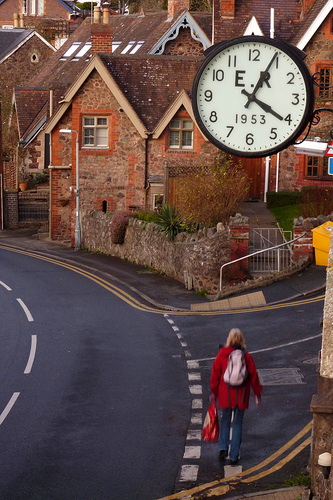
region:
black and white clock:
[191, 36, 311, 157]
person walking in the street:
[202, 327, 262, 465]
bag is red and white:
[199, 397, 220, 443]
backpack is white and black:
[221, 347, 250, 389]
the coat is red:
[209, 345, 262, 410]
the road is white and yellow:
[1, 242, 331, 499]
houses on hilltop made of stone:
[0, 1, 330, 246]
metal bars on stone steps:
[219, 232, 306, 297]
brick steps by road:
[17, 191, 50, 229]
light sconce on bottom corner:
[318, 451, 331, 480]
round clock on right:
[191, 36, 307, 152]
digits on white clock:
[208, 34, 299, 146]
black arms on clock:
[242, 72, 274, 126]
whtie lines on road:
[169, 390, 208, 467]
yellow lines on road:
[256, 411, 282, 483]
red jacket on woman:
[215, 352, 256, 411]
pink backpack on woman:
[223, 347, 253, 388]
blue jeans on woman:
[219, 410, 242, 451]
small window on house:
[82, 118, 117, 148]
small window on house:
[166, 118, 187, 146]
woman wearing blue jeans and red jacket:
[195, 326, 260, 466]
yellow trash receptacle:
[309, 222, 330, 270]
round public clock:
[191, 35, 317, 162]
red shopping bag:
[195, 403, 221, 442]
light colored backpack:
[220, 348, 249, 387]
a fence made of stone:
[72, 204, 331, 296]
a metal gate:
[252, 229, 294, 274]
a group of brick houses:
[2, 0, 331, 298]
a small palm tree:
[151, 204, 189, 244]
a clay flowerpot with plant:
[17, 172, 32, 193]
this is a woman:
[204, 327, 233, 450]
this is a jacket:
[200, 370, 287, 448]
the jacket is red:
[212, 386, 256, 399]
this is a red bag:
[187, 397, 215, 432]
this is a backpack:
[183, 342, 254, 404]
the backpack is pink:
[215, 333, 251, 399]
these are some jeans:
[211, 405, 237, 469]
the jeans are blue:
[213, 414, 242, 444]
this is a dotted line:
[156, 332, 168, 361]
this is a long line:
[230, 447, 289, 493]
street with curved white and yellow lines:
[2, 240, 329, 497]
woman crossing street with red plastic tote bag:
[198, 307, 266, 496]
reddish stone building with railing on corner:
[46, 77, 326, 314]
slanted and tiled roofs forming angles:
[1, 1, 332, 142]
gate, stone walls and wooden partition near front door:
[133, 154, 310, 291]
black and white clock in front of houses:
[142, 2, 331, 183]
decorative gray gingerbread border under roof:
[148, 9, 212, 62]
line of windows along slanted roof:
[24, 6, 143, 84]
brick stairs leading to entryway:
[10, 126, 54, 235]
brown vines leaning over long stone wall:
[77, 200, 229, 290]